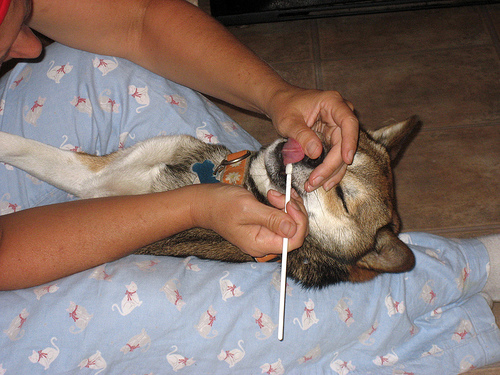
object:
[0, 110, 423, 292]
dog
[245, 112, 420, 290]
head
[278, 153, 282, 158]
teeth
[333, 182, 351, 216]
eye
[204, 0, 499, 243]
floor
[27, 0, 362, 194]
arm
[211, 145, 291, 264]
neck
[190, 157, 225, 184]
dog tag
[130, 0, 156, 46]
crease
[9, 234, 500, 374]
leg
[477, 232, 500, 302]
sock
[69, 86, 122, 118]
print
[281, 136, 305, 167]
tounge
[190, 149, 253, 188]
collar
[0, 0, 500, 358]
person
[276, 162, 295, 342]
q-tip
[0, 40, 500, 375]
pajama pants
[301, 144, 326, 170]
nose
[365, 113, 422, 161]
ear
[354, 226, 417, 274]
ear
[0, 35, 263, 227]
leg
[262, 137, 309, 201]
mouth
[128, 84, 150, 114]
cats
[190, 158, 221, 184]
bone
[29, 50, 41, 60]
top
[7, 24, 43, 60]
nose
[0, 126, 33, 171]
front paw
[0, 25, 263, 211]
lap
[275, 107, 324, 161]
finger